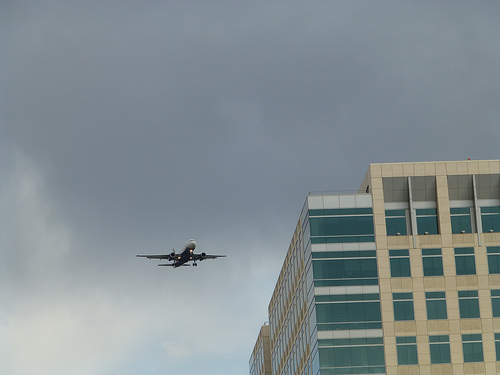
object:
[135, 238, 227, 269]
airplane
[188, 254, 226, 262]
wing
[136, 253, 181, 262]
wing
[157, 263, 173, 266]
side wing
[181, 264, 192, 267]
side wing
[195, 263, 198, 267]
wheels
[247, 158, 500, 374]
building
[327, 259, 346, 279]
window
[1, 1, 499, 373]
sky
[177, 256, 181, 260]
light